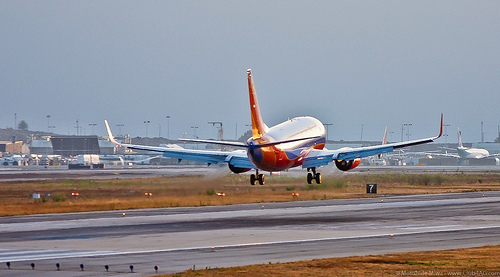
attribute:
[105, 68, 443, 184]
plane — landing, white, red, taking off, airborne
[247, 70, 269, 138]
tail — orange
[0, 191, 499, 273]
runway — smooth, gray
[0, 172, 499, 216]
field — brown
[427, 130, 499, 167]
plane — parked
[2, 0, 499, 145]
sky — clear, blue, hazy, gray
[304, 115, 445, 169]
wing — blue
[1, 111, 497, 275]
airport — busy